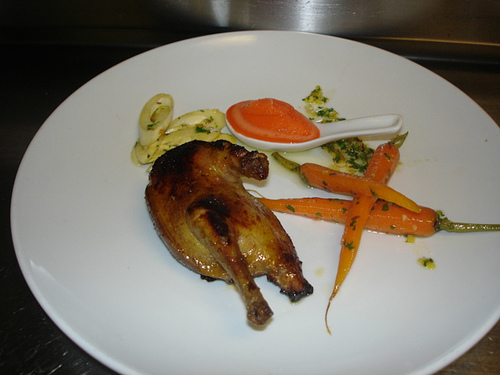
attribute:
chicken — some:
[172, 150, 284, 252]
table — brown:
[375, 23, 499, 72]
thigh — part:
[142, 138, 313, 327]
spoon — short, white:
[223, 112, 402, 151]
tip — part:
[312, 248, 360, 338]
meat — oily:
[141, 137, 316, 331]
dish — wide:
[10, 30, 499, 371]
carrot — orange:
[316, 192, 437, 234]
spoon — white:
[225, 97, 400, 150]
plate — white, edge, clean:
[8, 26, 493, 371]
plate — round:
[55, 42, 480, 354]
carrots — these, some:
[260, 129, 458, 250]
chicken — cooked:
[136, 140, 321, 332]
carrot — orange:
[274, 138, 494, 290]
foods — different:
[129, 78, 497, 333]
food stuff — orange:
[231, 100, 321, 149]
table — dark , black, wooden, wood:
[0, 9, 495, 369]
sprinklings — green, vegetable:
[278, 133, 414, 274]